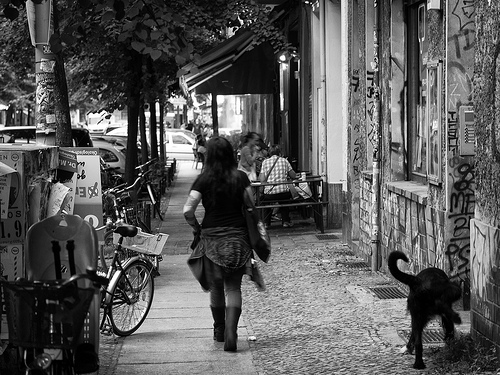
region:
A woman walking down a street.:
[180, 132, 277, 354]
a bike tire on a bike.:
[97, 248, 161, 340]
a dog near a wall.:
[367, 232, 472, 374]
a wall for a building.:
[340, 2, 498, 339]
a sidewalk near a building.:
[92, 132, 498, 374]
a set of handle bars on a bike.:
[74, 148, 185, 215]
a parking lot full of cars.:
[0, 119, 146, 208]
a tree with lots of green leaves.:
[41, 0, 257, 190]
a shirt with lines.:
[252, 132, 301, 210]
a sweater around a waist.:
[178, 232, 271, 299]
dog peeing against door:
[378, 244, 470, 374]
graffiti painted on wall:
[449, 7, 469, 309]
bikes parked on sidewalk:
[3, 152, 156, 361]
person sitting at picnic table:
[233, 155, 343, 237]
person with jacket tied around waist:
[179, 138, 260, 351]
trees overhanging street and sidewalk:
[0, 2, 222, 189]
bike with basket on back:
[92, 210, 171, 339]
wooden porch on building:
[176, 12, 297, 229]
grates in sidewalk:
[302, 228, 462, 353]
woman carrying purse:
[178, 138, 268, 358]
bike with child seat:
[17, 212, 103, 373]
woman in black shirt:
[180, 135, 272, 346]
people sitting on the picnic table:
[244, 134, 326, 220]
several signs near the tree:
[15, 138, 105, 212]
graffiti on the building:
[435, 37, 482, 263]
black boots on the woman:
[201, 285, 253, 349]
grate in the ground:
[365, 276, 403, 310]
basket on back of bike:
[126, 236, 173, 256]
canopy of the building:
[167, 46, 279, 95]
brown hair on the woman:
[196, 132, 236, 180]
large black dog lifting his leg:
[385, 252, 465, 371]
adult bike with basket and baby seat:
[0, 211, 101, 369]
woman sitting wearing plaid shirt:
[261, 139, 298, 229]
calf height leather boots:
[205, 298, 245, 348]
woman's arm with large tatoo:
[182, 182, 203, 245]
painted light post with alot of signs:
[28, 0, 60, 182]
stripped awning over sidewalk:
[175, 10, 307, 102]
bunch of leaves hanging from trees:
[58, 4, 173, 112]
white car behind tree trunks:
[113, 126, 196, 158]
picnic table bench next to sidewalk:
[252, 196, 328, 232]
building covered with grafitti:
[339, 0, 476, 298]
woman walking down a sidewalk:
[181, 135, 272, 354]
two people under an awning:
[176, 13, 307, 230]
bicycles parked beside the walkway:
[95, 156, 170, 345]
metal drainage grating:
[366, 282, 410, 302]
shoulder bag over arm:
[231, 168, 273, 265]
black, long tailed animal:
[386, 248, 466, 370]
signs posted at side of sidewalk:
[3, 145, 105, 336]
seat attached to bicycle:
[111, 220, 170, 257]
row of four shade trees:
[1, 0, 244, 197]